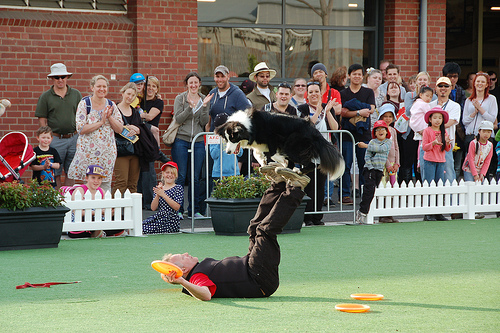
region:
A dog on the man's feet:
[218, 110, 345, 177]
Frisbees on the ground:
[334, 291, 383, 313]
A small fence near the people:
[364, 178, 498, 223]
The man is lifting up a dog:
[161, 164, 313, 299]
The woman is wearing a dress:
[68, 96, 124, 183]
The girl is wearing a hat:
[162, 162, 176, 170]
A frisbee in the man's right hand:
[148, 258, 185, 285]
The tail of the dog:
[317, 135, 346, 181]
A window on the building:
[198, 4, 381, 89]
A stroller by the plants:
[1, 132, 36, 180]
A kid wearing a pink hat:
[355, 118, 393, 220]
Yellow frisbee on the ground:
[333, 301, 368, 311]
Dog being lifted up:
[210, 107, 347, 182]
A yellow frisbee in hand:
[151, 258, 183, 277]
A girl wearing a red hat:
[142, 160, 184, 232]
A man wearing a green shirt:
[32, 60, 81, 185]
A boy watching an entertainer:
[29, 125, 62, 185]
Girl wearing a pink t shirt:
[420, 105, 450, 180]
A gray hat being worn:
[308, 62, 328, 76]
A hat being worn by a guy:
[247, 61, 277, 82]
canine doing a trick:
[211, 99, 356, 174]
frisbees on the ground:
[324, 255, 385, 312]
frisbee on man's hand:
[151, 256, 182, 288]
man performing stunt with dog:
[135, 160, 310, 300]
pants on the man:
[243, 183, 300, 274]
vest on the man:
[196, 255, 252, 295]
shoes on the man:
[255, 161, 308, 191]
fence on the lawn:
[363, 173, 498, 220]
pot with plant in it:
[200, 166, 317, 248]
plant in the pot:
[213, 170, 288, 198]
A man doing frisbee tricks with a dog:
[144, 101, 352, 308]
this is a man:
[153, 165, 320, 307]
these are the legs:
[245, 182, 300, 243]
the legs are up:
[235, 184, 305, 257]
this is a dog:
[216, 93, 323, 160]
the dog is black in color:
[273, 115, 306, 140]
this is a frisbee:
[148, 257, 182, 275]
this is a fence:
[83, 190, 139, 229]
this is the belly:
[213, 257, 249, 276]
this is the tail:
[310, 142, 342, 177]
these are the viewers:
[359, 62, 477, 162]